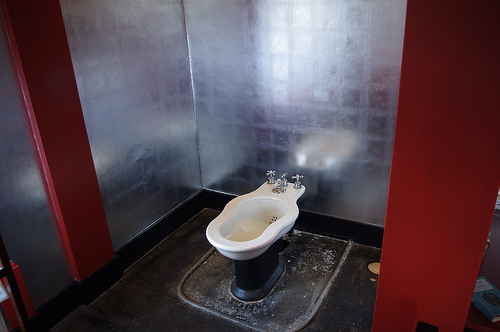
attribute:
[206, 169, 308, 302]
toilet — oddly shaped, short, white, porcelain, black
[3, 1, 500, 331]
bathroom — modern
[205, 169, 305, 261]
upper piece — white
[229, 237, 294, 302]
base — black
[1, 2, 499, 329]
walls — red, painted, silver, metallic, square-shaped, gray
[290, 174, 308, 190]
right sink faucet — silver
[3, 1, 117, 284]
plank — red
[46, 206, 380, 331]
floor — dirty, black, blackish brown, brown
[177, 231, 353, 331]
bottom — metal, black, silver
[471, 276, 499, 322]
book — blue, white, black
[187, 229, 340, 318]
specks — white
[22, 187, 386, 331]
baseboard — black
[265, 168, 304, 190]
faucets — metal, silver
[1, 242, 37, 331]
pipe — black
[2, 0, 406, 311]
paper — steel, stainless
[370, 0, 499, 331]
stall divider — red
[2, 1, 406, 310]
patterns — square